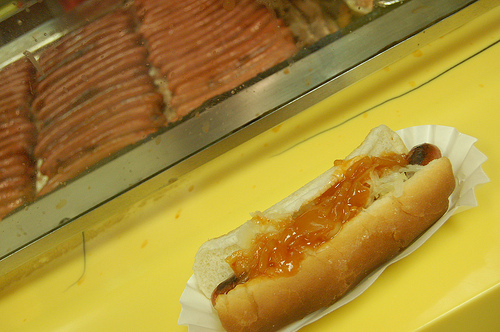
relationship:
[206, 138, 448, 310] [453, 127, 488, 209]
hot dog in paper wrap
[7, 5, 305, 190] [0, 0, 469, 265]
dogs cooking on grill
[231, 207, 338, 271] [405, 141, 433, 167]
ketchup on hot dog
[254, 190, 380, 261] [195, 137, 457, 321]
sauerkraut on hot dog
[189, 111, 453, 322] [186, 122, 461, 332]
hot dog on hotdog bun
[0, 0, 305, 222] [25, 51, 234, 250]
hot dog on grill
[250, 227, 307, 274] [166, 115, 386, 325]
sauce on hot dog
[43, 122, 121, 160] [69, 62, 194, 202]
hotdog in warmer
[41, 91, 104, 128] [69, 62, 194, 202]
hotdog in warmer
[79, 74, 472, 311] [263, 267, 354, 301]
weiner sticking out of bun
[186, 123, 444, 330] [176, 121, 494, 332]
hotdog bun in holder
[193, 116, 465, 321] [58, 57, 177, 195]
hot dogs in grill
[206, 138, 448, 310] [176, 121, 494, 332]
hot dog in holder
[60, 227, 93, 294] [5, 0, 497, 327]
crack in counter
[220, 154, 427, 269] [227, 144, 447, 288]
onions on hot dog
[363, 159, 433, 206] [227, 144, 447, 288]
sourkraut on hot dog